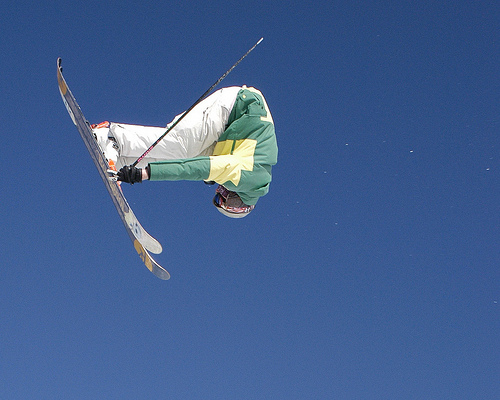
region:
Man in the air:
[35, 31, 311, 313]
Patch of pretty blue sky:
[425, 348, 468, 390]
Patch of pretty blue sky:
[322, 349, 377, 399]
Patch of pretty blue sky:
[225, 336, 330, 397]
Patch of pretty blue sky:
[125, 324, 208, 388]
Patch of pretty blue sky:
[382, 242, 444, 309]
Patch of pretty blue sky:
[273, 254, 348, 306]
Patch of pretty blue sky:
[185, 264, 380, 354]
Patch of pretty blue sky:
[53, 280, 158, 326]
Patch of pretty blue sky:
[345, 24, 423, 99]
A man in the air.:
[56, 37, 278, 282]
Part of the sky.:
[156, 340, 218, 370]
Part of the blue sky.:
[375, 76, 425, 123]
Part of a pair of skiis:
[55, 58, 83, 122]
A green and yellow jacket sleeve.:
[147, 160, 242, 185]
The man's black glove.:
[118, 165, 141, 182]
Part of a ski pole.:
[232, 38, 264, 67]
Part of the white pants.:
[116, 125, 150, 152]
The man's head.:
[214, 187, 254, 221]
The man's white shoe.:
[92, 122, 122, 169]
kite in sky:
[37, 59, 288, 287]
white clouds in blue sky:
[399, 43, 442, 78]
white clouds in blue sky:
[405, 62, 444, 113]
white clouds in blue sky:
[393, 291, 424, 328]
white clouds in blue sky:
[255, 300, 307, 359]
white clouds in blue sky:
[58, 309, 131, 365]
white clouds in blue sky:
[31, 194, 78, 246]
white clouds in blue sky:
[88, 12, 135, 69]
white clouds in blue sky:
[178, 238, 230, 268]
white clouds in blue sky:
[276, 274, 336, 350]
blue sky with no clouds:
[287, 302, 347, 358]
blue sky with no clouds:
[33, 294, 77, 337]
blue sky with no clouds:
[350, 314, 399, 349]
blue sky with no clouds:
[391, 283, 419, 320]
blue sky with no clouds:
[363, 130, 420, 185]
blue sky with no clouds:
[302, 82, 377, 168]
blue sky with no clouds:
[169, 335, 214, 361]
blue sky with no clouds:
[247, 285, 294, 350]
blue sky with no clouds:
[107, 325, 153, 349]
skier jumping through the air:
[45, 33, 276, 282]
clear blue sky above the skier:
[5, 3, 495, 394]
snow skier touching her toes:
[54, 42, 276, 281]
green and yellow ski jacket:
[150, 86, 277, 206]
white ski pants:
[86, 83, 238, 155]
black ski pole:
[119, 30, 261, 179]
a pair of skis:
[55, 58, 170, 284]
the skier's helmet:
[215, 193, 254, 217]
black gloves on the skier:
[118, 165, 144, 185]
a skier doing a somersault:
[51, 33, 277, 277]